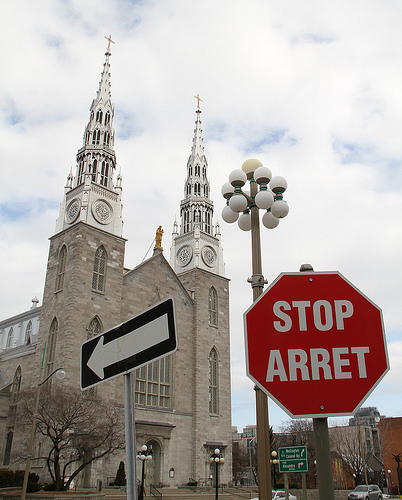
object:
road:
[20, 492, 401, 500]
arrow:
[86, 310, 169, 382]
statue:
[153, 224, 163, 251]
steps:
[57, 488, 259, 499]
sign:
[79, 295, 179, 389]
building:
[0, 34, 231, 489]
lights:
[241, 155, 263, 177]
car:
[346, 483, 381, 499]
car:
[246, 489, 297, 499]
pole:
[140, 462, 146, 499]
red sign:
[242, 268, 391, 420]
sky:
[0, 0, 402, 435]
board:
[242, 270, 391, 420]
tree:
[3, 380, 129, 491]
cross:
[103, 33, 116, 52]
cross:
[192, 93, 203, 108]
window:
[127, 352, 173, 407]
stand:
[301, 473, 307, 500]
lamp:
[54, 368, 67, 383]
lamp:
[140, 442, 147, 453]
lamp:
[213, 455, 219, 464]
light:
[259, 210, 281, 231]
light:
[252, 188, 276, 211]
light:
[234, 214, 254, 233]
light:
[266, 175, 289, 190]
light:
[252, 166, 270, 181]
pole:
[298, 263, 336, 498]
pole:
[284, 474, 291, 499]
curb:
[102, 491, 258, 499]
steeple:
[66, 34, 118, 187]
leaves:
[32, 395, 73, 417]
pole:
[249, 179, 273, 500]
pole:
[122, 370, 139, 498]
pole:
[214, 465, 219, 499]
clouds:
[0, 0, 401, 434]